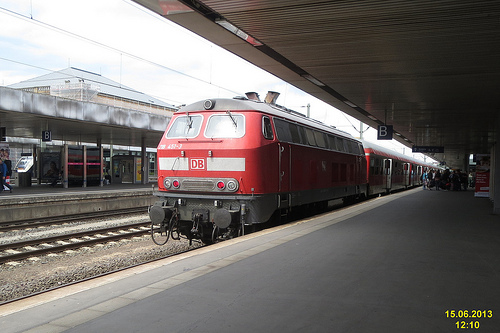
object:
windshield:
[165, 114, 246, 139]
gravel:
[0, 224, 202, 306]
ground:
[0, 209, 195, 298]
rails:
[0, 220, 167, 263]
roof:
[127, 0, 497, 168]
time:
[455, 320, 479, 328]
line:
[159, 157, 246, 171]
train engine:
[148, 91, 440, 246]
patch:
[159, 157, 188, 170]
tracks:
[2, 209, 174, 268]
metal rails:
[2, 206, 160, 264]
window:
[67, 145, 84, 163]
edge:
[249, 185, 369, 224]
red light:
[172, 179, 226, 190]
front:
[147, 99, 263, 245]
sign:
[377, 125, 394, 141]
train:
[148, 92, 449, 246]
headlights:
[164, 177, 240, 194]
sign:
[412, 145, 445, 153]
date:
[445, 309, 493, 318]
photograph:
[0, 0, 496, 330]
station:
[0, 24, 497, 333]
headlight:
[164, 176, 238, 192]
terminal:
[340, 99, 485, 252]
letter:
[190, 159, 204, 169]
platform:
[0, 187, 500, 333]